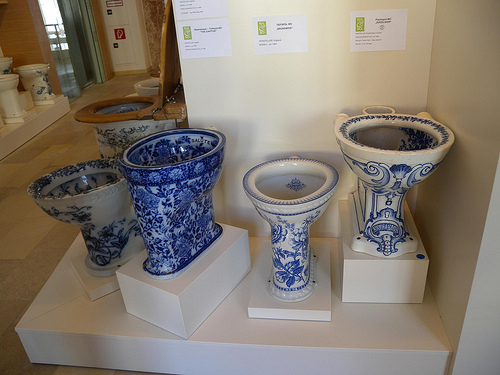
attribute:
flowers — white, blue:
[136, 186, 209, 242]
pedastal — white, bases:
[337, 194, 427, 303]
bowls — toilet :
[332, 106, 457, 258]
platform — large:
[11, 219, 432, 371]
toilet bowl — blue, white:
[90, 97, 179, 160]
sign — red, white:
[111, 26, 129, 40]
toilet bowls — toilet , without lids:
[1, 116, 483, 313]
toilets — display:
[58, 82, 430, 339]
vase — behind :
[330, 102, 455, 278]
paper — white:
[347, 6, 409, 51]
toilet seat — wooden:
[72, 15, 174, 167]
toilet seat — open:
[49, 2, 184, 132]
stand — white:
[116, 221, 252, 337]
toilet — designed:
[240, 153, 340, 305]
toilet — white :
[239, 157, 396, 294]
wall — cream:
[174, 2, 438, 236]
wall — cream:
[414, 0, 498, 374]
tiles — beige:
[11, 218, 53, 242]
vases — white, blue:
[146, 128, 423, 268]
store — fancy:
[2, 1, 498, 372]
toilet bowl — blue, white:
[28, 155, 146, 277]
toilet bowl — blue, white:
[117, 126, 227, 278]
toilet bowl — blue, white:
[243, 154, 339, 302]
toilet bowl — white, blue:
[333, 104, 456, 259]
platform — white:
[13, 229, 449, 374]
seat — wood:
[72, 92, 160, 122]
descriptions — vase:
[179, 12, 405, 59]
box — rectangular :
[116, 221, 252, 340]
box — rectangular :
[249, 235, 331, 322]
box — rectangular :
[338, 198, 429, 304]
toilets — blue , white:
[336, 102, 458, 260]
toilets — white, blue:
[241, 151, 345, 302]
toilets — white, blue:
[119, 126, 231, 277]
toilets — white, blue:
[29, 154, 146, 276]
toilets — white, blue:
[78, 85, 190, 165]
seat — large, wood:
[57, 100, 147, 123]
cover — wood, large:
[139, 6, 176, 107]